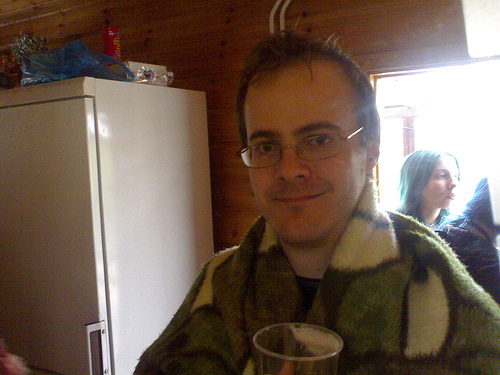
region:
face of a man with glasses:
[231, 38, 383, 245]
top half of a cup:
[251, 320, 344, 374]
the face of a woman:
[400, 147, 461, 217]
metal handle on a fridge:
[83, 320, 115, 373]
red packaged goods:
[103, 25, 121, 65]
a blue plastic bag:
[21, 45, 131, 82]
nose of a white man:
[274, 155, 309, 182]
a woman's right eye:
[435, 168, 447, 181]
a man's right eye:
[247, 137, 282, 162]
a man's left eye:
[305, 129, 338, 152]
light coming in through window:
[375, 53, 476, 239]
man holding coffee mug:
[185, 329, 417, 371]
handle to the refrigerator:
[47, 251, 130, 369]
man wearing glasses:
[235, 97, 435, 189]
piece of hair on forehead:
[288, 55, 358, 90]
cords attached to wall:
[253, 3, 305, 25]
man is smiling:
[263, 176, 365, 216]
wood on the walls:
[208, 60, 244, 241]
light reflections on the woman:
[377, 130, 497, 270]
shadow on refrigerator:
[126, 128, 236, 207]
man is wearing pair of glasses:
[222, 26, 379, 242]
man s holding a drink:
[233, 308, 346, 373]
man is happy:
[230, 30, 385, 251]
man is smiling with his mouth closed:
[227, 27, 385, 247]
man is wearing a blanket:
[136, 196, 484, 366]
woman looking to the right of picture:
[398, 143, 464, 221]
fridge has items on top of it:
[5, 20, 218, 105]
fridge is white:
[0, 75, 216, 372]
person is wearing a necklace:
[447, 175, 497, 262]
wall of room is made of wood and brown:
[2, 17, 499, 75]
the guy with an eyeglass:
[155, 61, 465, 291]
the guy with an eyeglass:
[209, 65, 385, 233]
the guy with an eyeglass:
[191, 22, 364, 167]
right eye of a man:
[251, 138, 277, 154]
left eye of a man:
[304, 133, 334, 147]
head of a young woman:
[406, 150, 458, 217]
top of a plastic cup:
[251, 325, 343, 373]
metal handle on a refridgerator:
[81, 321, 111, 373]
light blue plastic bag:
[24, 43, 134, 82]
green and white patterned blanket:
[343, 237, 435, 374]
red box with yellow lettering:
[104, 25, 120, 60]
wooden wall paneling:
[143, 1, 246, 66]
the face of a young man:
[237, 34, 380, 242]